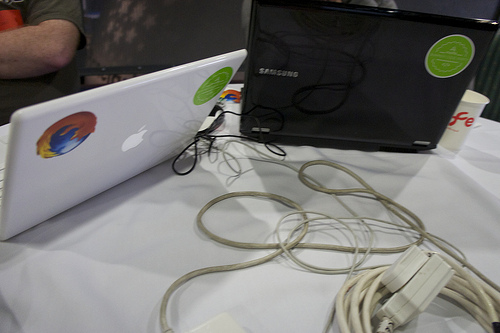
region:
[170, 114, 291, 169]
Black cord on a white table top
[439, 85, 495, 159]
White and red coffee cup on table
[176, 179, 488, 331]
Beige power cords on a white table top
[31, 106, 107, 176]
Firefox sticker on an Apple computer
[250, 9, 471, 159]
Black Samsung laptop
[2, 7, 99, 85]
Man with arm folded across chest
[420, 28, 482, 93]
Green sticker on Samsung laptop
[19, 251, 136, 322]
White table top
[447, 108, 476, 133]
Red letters on a white cup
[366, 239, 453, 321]
Power cord with outlet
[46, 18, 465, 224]
Two laptop are in table.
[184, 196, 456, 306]
Wires are white color.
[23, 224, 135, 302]
Table is white color.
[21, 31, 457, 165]
Stickers are attached to the outer surface of laptop.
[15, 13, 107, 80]
One man is sitting in front of laptop.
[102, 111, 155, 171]
White laptop is apple brand.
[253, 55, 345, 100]
Black laptop is samsung brand.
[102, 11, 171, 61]
Star design in wall.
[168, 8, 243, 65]
Wall is grey color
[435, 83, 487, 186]
cup is in table.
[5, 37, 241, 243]
a white computer Apple on a table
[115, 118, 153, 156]
logotype of Apple on a computer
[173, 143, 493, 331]
coiled wires on a table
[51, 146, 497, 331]
table is cover with a white tablecloth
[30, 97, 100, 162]
yellow and blue sticker on corner of computer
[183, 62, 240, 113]
green sticker on right corner of computer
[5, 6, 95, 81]
the elbow of a person in front of computer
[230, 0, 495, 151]
a black Samsung laptop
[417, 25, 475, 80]
green sticker on right corner of computer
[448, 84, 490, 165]
a white cup next a black computer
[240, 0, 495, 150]
Samsung's black laptop computer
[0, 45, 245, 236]
a white Apple laptop computer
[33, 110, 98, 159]
Mozilla Firefox icon on the back of the laptop's monitor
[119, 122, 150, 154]
an Apple icon on the white computer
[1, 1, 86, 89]
the arm of a man sitting in a chair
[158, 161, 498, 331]
cords and an adapter on the table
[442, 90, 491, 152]
a white paper cup beside the black laptop computer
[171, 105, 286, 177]
the power cord to the black laptop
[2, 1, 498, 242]
two laptop computers on a table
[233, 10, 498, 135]
Black Windows Samsung laptop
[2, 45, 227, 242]
White Apple laptop with a green sticker and Firefox sticker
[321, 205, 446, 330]
White extension cord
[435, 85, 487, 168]
White and orange coffee cup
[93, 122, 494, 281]
White tablecloth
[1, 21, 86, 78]
Man's hairy arm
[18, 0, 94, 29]
Forrest green t-shirt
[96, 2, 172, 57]
Star lights on the wall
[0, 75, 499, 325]
Medium-sized round table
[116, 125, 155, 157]
Apple logo